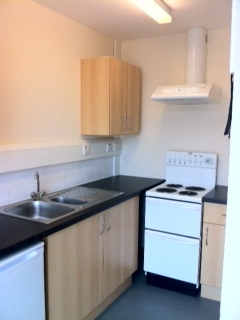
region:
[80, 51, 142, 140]
overhead wood cabinets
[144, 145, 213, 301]
a slim white stove and oven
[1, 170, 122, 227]
a brushed aluminum sink basin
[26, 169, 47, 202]
a chrome kitchen fauced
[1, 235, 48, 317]
a white diswasher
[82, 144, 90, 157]
a white electrical wall outlet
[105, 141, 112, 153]
a white electrical wall outlet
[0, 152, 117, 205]
a white tile backsplash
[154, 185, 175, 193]
a black electric burner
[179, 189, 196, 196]
a black electric burner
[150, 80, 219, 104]
a white electric vent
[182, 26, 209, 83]
a white ventilation tube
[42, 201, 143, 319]
under sink cabinets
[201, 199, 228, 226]
a wooden drawer with pull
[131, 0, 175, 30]
an overhead fluorescent light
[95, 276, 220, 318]
a dark grey floor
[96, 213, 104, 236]
a metal drawer pull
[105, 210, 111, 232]
a metal drawer pull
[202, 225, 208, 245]
a metal drawer pull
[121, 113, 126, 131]
a metal drawer pull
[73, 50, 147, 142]
A wooden cabinet hangs on the wall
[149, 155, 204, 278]
White stove with four burners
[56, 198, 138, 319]
The cabinet has two doors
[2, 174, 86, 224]
The sink is silver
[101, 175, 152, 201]
The counter top is dark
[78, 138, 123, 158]
There are outlets on the wall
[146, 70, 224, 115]
A vent is above the stove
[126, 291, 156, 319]
The floor is blue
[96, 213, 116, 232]
The handles are on the cupboard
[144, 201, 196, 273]
There is a door on the front of the stove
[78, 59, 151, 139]
The wooden cabinet mounted on the wall.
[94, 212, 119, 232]
The door handles of the cabinets under the sink.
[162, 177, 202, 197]
The four burners on the stove.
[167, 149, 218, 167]
The panel of buttons on the stove.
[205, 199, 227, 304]
The cabinet to the right of the stove.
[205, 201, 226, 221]
The drawer on the cabinet to the right of the stove.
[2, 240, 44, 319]
The white dishwasher on the left.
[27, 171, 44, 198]
The faucet and knobs to the sink.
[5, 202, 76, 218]
The larger sink on the left.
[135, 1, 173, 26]
The long panel light on the ceiling.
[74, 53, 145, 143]
two light brown wooden cabinets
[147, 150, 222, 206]
white stove top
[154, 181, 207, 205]
four electric stove stop burners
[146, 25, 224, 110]
shiny white hood fan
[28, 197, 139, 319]
two light brown wooden cabinets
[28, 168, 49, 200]
silver metal kitchen faucet fixture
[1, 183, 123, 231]
shiny silver metal kitchen sink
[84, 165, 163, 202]
section of black counter top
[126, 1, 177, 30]
fluorescent tubing light fixture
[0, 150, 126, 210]
white tiled back splash